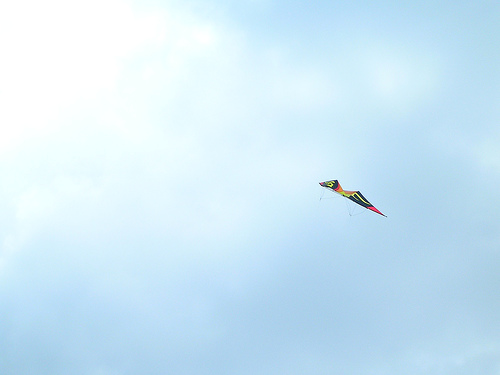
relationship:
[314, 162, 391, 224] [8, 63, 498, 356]
kite in sky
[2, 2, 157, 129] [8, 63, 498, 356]
clouds in sky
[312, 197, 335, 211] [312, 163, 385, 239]
string on kite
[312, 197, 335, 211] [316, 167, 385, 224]
string on kite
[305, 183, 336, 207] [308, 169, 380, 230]
string on kite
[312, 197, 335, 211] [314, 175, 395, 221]
string on plane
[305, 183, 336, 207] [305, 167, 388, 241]
string on kite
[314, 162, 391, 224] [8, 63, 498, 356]
kite on sky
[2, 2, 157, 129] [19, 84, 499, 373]
clouds in sky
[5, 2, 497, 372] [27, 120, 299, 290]
sky with clouds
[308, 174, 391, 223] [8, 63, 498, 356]
glider in sky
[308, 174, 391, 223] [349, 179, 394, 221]
glider with wing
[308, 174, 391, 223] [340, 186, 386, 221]
glider with wing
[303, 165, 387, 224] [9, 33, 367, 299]
kite flying in air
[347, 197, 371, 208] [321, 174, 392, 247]
white lines in kite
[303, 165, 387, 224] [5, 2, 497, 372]
kite in sky